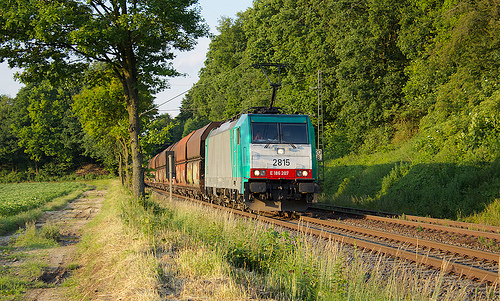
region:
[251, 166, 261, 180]
a headlight on the train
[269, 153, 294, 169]
black numbers on the train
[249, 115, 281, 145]
the windshield of the train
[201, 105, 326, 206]
a green train engine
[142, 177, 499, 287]
a pair of train tracks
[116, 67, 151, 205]
the trunk of a tree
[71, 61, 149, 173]
a green leafy tree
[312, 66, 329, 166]
a gray metal pole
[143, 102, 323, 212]
a long train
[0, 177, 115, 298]
a dirt road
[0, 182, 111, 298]
a brown dirt road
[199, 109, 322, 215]
the engine of a train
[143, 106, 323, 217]
a train on the tracks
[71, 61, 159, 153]
a green tree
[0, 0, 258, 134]
a clear blue sky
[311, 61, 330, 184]
a gray metal post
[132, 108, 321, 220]
A train coming down the tracks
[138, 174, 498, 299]
The brown metal train tracks with gravel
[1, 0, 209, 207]
A tree growing beside the train tracks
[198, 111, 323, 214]
A blue and grey front car of a train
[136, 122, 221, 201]
The rusted metal cars carried along by the train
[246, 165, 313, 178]
Headlights on the front of the train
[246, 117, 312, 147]
A window on the front of the train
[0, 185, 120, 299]
A dirt path beside the tracks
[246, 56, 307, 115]
A pole holding up wires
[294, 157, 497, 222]
The shadow of the train to its right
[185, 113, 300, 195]
this is a train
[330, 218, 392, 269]
this is the railway line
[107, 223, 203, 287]
this is a grass area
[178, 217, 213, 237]
the grass is green in color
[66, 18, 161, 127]
this is a tree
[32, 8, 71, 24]
the tree has green leaves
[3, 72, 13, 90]
this is the sky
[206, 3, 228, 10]
the sky is blue in color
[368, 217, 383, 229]
these are small rocks in between the lines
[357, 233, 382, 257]
this is a metal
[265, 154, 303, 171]
the number on train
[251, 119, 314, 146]
the front windows on train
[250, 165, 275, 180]
lights on front of train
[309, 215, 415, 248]
part of the railroad tracks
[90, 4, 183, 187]
part of tree near train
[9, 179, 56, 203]
grassy area near train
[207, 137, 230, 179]
side portion of train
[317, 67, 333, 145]
ladder tower next to train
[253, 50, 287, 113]
contraption on top of train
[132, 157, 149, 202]
the trunk of tree